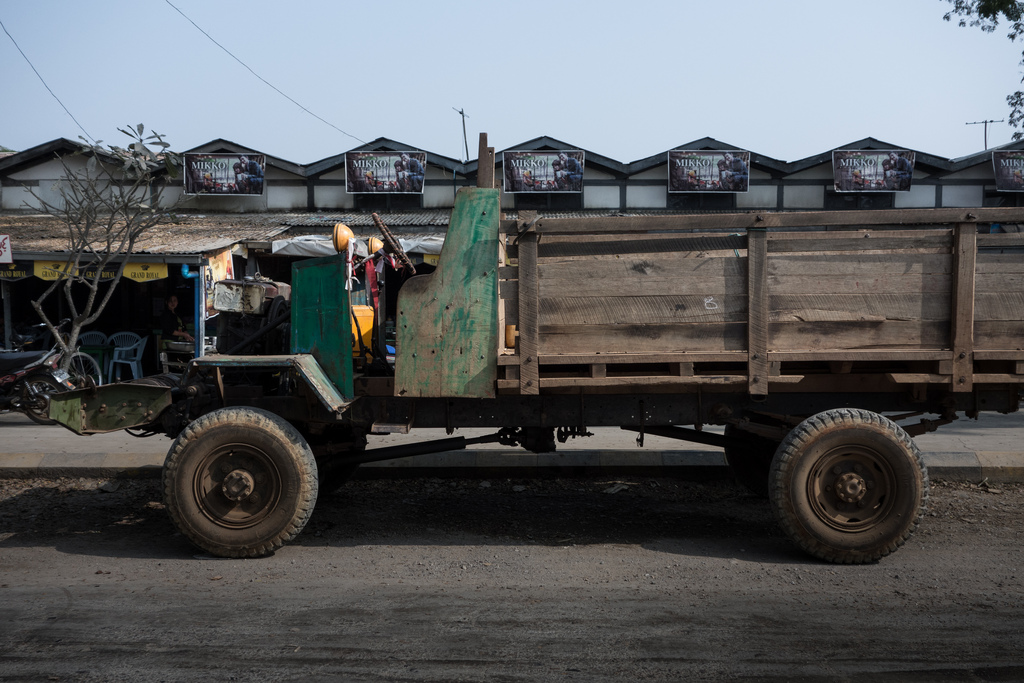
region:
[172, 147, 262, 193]
sign on the building behind truck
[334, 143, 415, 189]
sign on the building behind truck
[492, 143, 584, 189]
sign on the building behind truck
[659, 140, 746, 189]
sign on the building behind truck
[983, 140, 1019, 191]
sign on the building behind truck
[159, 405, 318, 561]
wheel on old truck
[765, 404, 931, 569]
wheel on old truck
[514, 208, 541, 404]
wood post on bed of the truck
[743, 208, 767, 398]
wood post on bed of the truck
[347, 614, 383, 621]
this picture is taken outdoorsthis picture is taken outdoors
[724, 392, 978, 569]
front tire on truckthe back tire on truck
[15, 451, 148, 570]
a shadow on the road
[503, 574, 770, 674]
the road is black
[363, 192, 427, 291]
a brown steering wheel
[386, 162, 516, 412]
the side door is green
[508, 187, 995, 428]
the bed of truck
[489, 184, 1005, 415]
the truck bed is wood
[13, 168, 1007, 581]
a old work truck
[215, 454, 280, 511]
a hubcap on wheel